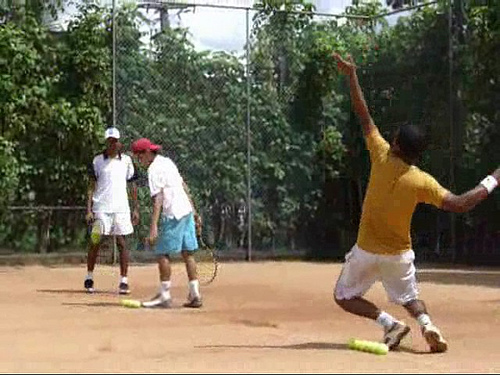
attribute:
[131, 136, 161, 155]
cap — red, worn backwards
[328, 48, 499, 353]
man — serving, playing tennis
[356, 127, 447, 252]
shirt — yellow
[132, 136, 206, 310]
man — standing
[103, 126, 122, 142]
cap — white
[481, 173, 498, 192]
sweat band — white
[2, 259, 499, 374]
tennis court — clay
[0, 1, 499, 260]
fence — tall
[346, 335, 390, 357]
tennis balls — in a line, green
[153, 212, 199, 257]
shorts — blue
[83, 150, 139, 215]
shirt — white, black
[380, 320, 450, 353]
shoes — white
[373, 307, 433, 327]
socks — white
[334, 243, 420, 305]
shorts — white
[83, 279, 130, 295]
shoes — black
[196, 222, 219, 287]
tennis racket — black